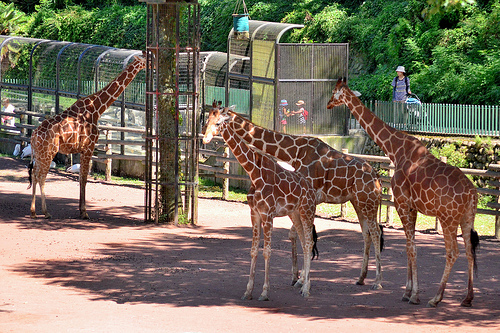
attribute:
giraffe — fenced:
[324, 77, 486, 254]